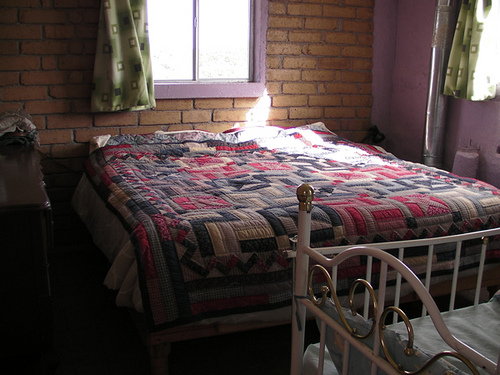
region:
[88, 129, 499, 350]
quilt on a bed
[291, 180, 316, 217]
gold post on a bed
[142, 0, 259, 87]
window above a bed with a quilt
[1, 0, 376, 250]
wall made of brick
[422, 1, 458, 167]
silver pipe running on a wall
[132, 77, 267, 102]
pink window sill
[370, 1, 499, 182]
pink painted wall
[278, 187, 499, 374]
white framed child's bed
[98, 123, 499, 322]
quilt on the bed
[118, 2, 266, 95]
window above the bed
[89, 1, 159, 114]
green patterned curtain on the window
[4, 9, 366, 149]
brick wall bed is against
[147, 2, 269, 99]
frame of the window above the bed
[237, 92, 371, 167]
sunlight on the wall and quilt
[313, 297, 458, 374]
pillow on child's bed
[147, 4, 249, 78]
sunlight coming thru window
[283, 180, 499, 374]
metal barred baby crib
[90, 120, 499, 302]
red, white and blue quilted bedspread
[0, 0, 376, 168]
red brick wall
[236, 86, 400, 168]
sunlight falling on wall and quilt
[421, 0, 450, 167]
aluminum pipe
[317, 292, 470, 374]
pillow at the head of the crib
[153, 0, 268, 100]
window framing painted purple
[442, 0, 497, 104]
light reflecting off of green checked curtain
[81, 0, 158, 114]
green fabric curtain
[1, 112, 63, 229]
wooden bedside table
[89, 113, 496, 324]
this is a bed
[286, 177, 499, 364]
this is a bed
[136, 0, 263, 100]
this is a window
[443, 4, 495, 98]
this is a window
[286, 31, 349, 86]
these are bricks on a wall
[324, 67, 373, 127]
these are bricks on a wall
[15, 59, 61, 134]
these are bricks on a wall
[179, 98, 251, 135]
these are bricks on a wall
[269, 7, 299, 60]
these are bricks on a wall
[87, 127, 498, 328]
The pink colored quilt on the bed.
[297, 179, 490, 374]
The foot board of the day bed.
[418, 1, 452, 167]
The silver/chrome pipe on the wall.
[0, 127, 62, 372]
The dark brown dresser on the left.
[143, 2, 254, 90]
The window above the bed.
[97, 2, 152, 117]
The green curtain above the bed.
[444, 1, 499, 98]
The green curtain on the right.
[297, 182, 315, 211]
The gold ball on the white bed.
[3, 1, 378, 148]
The brick wall the bed is up against.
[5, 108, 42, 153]
The folded clothing on top of the brown dresser.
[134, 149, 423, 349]
the blanket is quilted